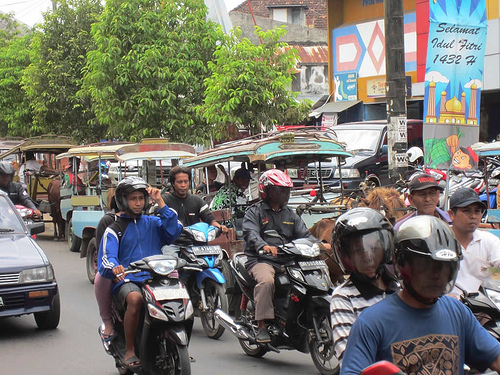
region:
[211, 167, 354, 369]
The man is riding a motorcycle.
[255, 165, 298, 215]
The man is wearing a helmet.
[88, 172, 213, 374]
There are two people riding the motorcycle.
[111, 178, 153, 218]
The man is wearing a helmet.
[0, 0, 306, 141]
The trees are green.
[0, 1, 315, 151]
The trees are full of leaves.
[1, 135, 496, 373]
The street is very congested.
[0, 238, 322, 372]
The roadway is dry.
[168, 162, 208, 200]
The man is not wearing a helmet.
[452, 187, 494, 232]
The man is wearing a baseball cap.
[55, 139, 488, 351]
many people riding motorcycles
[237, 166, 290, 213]
red graphic motorcycle helmet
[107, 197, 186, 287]
blue track jacket on person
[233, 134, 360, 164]
green top of bus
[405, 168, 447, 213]
black hat with red writing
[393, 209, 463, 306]
black and silver helmet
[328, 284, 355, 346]
black and white striped top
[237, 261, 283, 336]
man wearing khaki pants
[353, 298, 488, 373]
blue graphic print shirt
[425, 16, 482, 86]
advertising hanging on building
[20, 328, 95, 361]
clear gray street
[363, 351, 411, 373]
pink handle of bike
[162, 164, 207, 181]
man's short black curly hair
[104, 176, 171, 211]
man wearing black helmet with white stripe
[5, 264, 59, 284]
front headlights on gray car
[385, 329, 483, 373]
black and tan symbol on blue tee shirt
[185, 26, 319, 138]
small green tree on sidewalk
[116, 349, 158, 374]
black flip flops on man's feet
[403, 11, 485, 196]
large square blue and green banner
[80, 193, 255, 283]
blue and black jacket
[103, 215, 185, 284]
Blue wind breaker with white stripes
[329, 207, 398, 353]
Woman wearing helmet with visor down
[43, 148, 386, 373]
Group of people riding scooters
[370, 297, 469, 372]
Man with blue shirt with tan and gold design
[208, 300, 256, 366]
Silver muffler on scooter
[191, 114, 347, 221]
Rusty blue bus on street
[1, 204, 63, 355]
Blue car on crowded street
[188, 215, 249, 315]
Blue scooter with headlights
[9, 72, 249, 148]
Green trees on side of street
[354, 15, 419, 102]
Sign with a red triangle and white base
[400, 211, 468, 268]
the helmet is black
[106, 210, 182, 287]
his top is blue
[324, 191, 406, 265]
the cart is being driven by a horse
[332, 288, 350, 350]
the man has a striped top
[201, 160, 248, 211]
the man is in a cart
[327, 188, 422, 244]
the horse is brown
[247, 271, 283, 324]
the man is in khaki pants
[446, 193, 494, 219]
the man has a black hat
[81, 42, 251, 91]
the trees are green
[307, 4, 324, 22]
the walls are brown